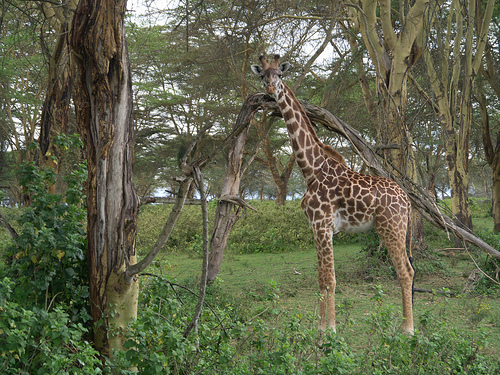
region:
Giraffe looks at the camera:
[242, 39, 453, 372]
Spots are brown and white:
[318, 162, 371, 222]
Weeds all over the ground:
[238, 267, 318, 374]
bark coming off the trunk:
[94, 140, 138, 373]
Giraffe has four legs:
[283, 263, 419, 373]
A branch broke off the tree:
[162, 147, 253, 370]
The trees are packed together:
[135, 28, 236, 160]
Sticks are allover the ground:
[427, 237, 497, 349]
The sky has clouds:
[124, 1, 221, 108]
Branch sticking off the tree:
[112, 208, 213, 315]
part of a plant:
[292, 312, 336, 354]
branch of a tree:
[128, 235, 162, 288]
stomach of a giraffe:
[338, 167, 375, 219]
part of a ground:
[278, 260, 309, 320]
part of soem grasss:
[283, 249, 323, 296]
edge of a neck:
[292, 155, 312, 184]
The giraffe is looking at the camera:
[246, 46, 303, 106]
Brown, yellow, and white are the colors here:
[231, 53, 445, 344]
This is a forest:
[11, 11, 483, 367]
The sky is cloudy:
[37, 5, 479, 206]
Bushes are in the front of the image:
[11, 130, 462, 370]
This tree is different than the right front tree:
[343, 12, 491, 249]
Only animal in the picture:
[240, 42, 470, 354]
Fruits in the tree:
[11, 103, 152, 318]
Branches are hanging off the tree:
[120, 113, 312, 343]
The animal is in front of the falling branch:
[207, 46, 498, 323]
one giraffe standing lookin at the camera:
[249, 54, 417, 346]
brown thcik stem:
[43, 7, 131, 355]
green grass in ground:
[30, 190, 497, 371]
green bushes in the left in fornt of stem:
[5, 131, 143, 361]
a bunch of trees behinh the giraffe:
[0, 8, 491, 209]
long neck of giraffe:
[269, 72, 327, 166]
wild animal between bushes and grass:
[255, 54, 425, 351]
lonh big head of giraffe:
[252, 50, 287, 111]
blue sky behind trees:
[3, 7, 494, 188]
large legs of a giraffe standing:
[313, 221, 418, 341]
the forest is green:
[122, 71, 420, 369]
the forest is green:
[183, 124, 360, 356]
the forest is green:
[136, 97, 281, 289]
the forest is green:
[161, 30, 311, 226]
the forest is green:
[86, 63, 267, 353]